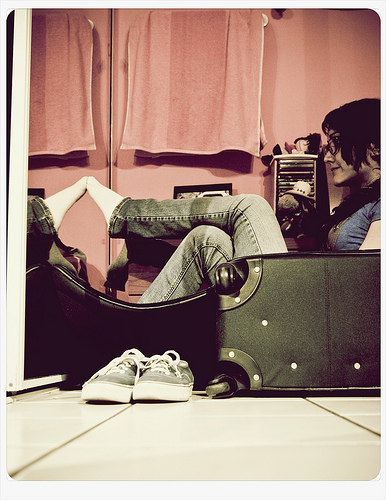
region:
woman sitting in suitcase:
[106, 112, 371, 311]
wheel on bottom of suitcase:
[202, 348, 257, 403]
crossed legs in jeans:
[161, 190, 286, 281]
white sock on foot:
[80, 172, 136, 240]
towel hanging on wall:
[115, 19, 277, 166]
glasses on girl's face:
[314, 129, 347, 164]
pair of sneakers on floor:
[75, 338, 194, 408]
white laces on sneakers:
[106, 339, 177, 379]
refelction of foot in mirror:
[59, 173, 116, 217]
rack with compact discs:
[269, 151, 320, 208]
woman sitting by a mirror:
[89, 78, 375, 393]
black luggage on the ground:
[206, 242, 380, 415]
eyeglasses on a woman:
[314, 131, 343, 158]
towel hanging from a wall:
[119, 11, 272, 165]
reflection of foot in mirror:
[33, 172, 87, 244]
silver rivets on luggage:
[281, 355, 369, 375]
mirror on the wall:
[31, 50, 119, 181]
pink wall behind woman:
[282, 18, 377, 104]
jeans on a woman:
[117, 189, 279, 254]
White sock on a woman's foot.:
[84, 175, 125, 226]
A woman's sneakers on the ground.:
[80, 345, 194, 403]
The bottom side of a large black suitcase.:
[204, 246, 381, 398]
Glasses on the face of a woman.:
[319, 136, 347, 158]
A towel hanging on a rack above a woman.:
[115, 4, 269, 164]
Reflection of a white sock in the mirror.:
[40, 168, 89, 230]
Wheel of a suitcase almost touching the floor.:
[204, 373, 232, 397]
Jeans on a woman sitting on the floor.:
[109, 193, 289, 304]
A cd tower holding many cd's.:
[264, 151, 319, 237]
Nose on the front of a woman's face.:
[321, 145, 335, 164]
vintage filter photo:
[0, 2, 384, 490]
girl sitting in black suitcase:
[52, 71, 378, 395]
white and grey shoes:
[85, 342, 198, 407]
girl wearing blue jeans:
[110, 95, 385, 304]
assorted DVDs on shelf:
[272, 151, 320, 235]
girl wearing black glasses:
[88, 87, 384, 304]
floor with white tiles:
[13, 377, 383, 482]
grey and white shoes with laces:
[84, 342, 194, 405]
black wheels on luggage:
[206, 255, 249, 398]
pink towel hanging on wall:
[122, 10, 266, 154]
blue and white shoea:
[61, 335, 207, 429]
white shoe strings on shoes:
[60, 338, 190, 377]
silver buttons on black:
[240, 307, 332, 404]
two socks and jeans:
[31, 169, 128, 240]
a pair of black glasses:
[305, 119, 342, 162]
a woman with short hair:
[314, 84, 380, 184]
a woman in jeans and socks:
[89, 162, 311, 323]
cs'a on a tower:
[258, 147, 321, 221]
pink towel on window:
[111, 0, 274, 167]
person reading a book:
[27, 86, 361, 308]